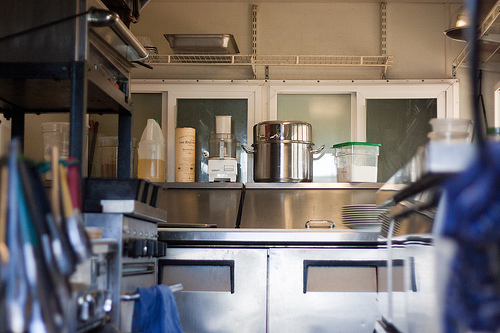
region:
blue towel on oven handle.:
[142, 290, 168, 319]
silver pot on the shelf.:
[255, 123, 314, 176]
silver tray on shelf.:
[171, 31, 236, 48]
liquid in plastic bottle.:
[142, 119, 162, 171]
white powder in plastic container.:
[345, 157, 378, 180]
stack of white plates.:
[347, 205, 374, 230]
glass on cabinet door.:
[381, 112, 421, 151]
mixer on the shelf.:
[211, 136, 235, 174]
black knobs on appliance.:
[126, 240, 159, 254]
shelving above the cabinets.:
[277, 54, 385, 67]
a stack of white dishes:
[339, 194, 393, 242]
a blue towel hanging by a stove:
[118, 276, 188, 331]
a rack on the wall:
[141, 31, 392, 78]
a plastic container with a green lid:
[329, 126, 385, 195]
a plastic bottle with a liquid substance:
[129, 116, 170, 189]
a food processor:
[203, 105, 246, 192]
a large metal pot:
[250, 107, 327, 197]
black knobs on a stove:
[117, 234, 173, 266]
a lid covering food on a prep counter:
[235, 174, 421, 243]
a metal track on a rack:
[156, 24, 254, 63]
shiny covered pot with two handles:
[239, 113, 327, 183]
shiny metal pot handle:
[313, 142, 328, 159]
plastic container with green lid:
[328, 136, 385, 184]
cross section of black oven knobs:
[117, 231, 170, 263]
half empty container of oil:
[131, 115, 169, 181]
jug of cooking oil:
[136, 113, 170, 183]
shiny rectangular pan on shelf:
[159, 27, 244, 67]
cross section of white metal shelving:
[159, 54, 394, 69]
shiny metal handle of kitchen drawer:
[301, 218, 340, 232]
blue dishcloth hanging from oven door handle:
[134, 283, 184, 331]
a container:
[327, 127, 391, 202]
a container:
[417, 102, 477, 176]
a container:
[435, 105, 466, 155]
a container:
[318, 131, 366, 183]